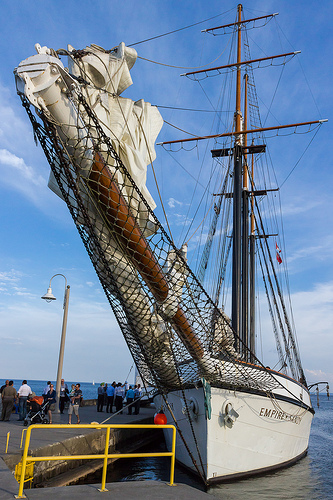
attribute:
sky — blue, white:
[0, 0, 331, 393]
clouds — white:
[0, 81, 331, 394]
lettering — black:
[258, 408, 303, 423]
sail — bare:
[154, 2, 328, 391]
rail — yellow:
[16, 419, 177, 498]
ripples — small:
[214, 416, 331, 498]